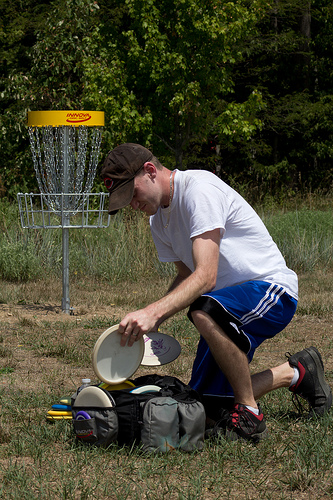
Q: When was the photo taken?
A: Daytime.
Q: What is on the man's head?
A: A hat.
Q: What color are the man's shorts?
A: Blue with white stripes.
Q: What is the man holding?
A: Discs.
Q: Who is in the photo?
A: A man.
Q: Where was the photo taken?
A: A disc golf course.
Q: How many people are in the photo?
A: One.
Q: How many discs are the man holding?
A: Two.